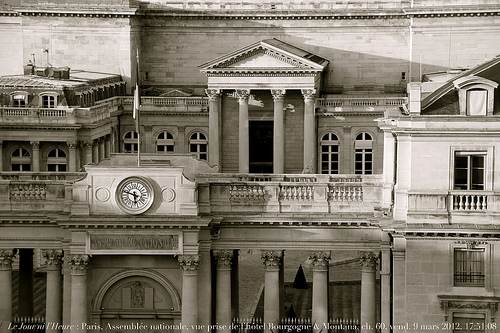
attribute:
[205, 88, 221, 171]
column — white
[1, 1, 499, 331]
building — brick, gray, large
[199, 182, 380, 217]
rail — gray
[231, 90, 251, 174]
pillar — gray, white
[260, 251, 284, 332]
column — gray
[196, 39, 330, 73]
roof — triangular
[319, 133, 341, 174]
window — arched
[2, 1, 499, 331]
mansion — white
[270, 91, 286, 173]
pillar — white